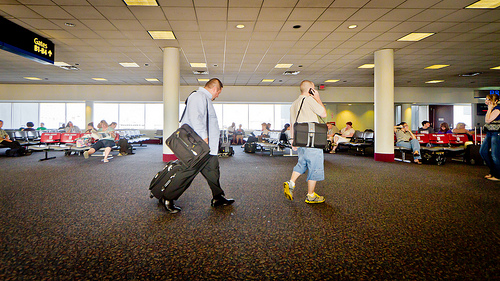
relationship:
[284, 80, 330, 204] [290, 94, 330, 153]
man carrying bag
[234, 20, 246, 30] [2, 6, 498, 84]
light in ceiling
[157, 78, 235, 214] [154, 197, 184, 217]
man wearing shoe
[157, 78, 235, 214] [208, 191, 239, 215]
man wearing shoe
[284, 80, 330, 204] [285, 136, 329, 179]
man wearing shorts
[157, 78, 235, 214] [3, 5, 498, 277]
man walking through airport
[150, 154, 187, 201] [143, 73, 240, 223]
bags behind man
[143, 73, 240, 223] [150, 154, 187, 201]
man has bags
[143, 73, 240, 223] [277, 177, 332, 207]
man wearing shoes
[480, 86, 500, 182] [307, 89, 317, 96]
woman on cell phone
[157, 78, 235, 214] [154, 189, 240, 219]
man has shoes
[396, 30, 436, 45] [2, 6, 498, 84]
lights on ceiling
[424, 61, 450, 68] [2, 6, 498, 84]
lights on ceiling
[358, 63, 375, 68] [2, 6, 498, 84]
lights on ceiling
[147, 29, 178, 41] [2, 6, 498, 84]
lights on ceiling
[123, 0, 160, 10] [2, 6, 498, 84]
lights on ceiling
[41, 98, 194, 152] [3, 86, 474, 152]
sun shinine through windows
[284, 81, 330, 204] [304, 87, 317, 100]
man talking on cell phone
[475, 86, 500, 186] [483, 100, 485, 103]
woman talking on phone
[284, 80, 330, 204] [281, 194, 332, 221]
man walking on floor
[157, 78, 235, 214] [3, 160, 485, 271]
man walking on floor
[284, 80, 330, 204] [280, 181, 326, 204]
man wearing shoes